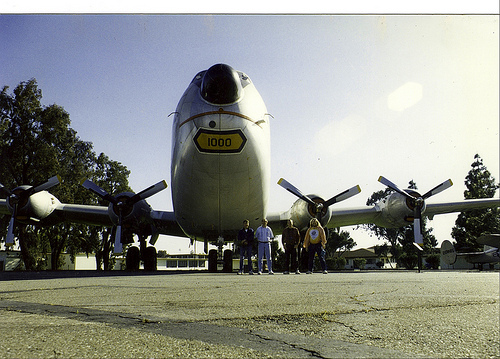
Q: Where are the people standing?
A: Under the plane.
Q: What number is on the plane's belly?
A: 1000.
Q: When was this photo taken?
A: During the day.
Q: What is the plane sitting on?
A: Concrete.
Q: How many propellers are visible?
A: Four.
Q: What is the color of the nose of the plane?
A: Black.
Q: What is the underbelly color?
A: Silver.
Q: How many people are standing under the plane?
A: Four.